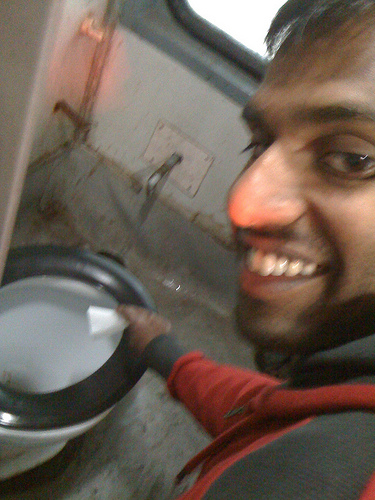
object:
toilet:
[2, 225, 178, 500]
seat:
[47, 256, 96, 270]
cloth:
[85, 299, 131, 344]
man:
[102, 0, 375, 499]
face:
[218, 7, 375, 351]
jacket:
[139, 289, 375, 500]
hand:
[86, 293, 179, 360]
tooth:
[271, 254, 290, 278]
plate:
[140, 116, 218, 199]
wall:
[130, 71, 179, 117]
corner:
[184, 0, 204, 19]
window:
[163, 0, 298, 91]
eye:
[305, 129, 375, 191]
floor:
[138, 402, 170, 461]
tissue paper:
[79, 301, 134, 344]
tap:
[145, 175, 159, 196]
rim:
[225, 42, 233, 54]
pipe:
[144, 150, 184, 199]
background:
[0, 1, 375, 286]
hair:
[285, 7, 297, 17]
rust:
[52, 197, 60, 211]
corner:
[49, 193, 61, 209]